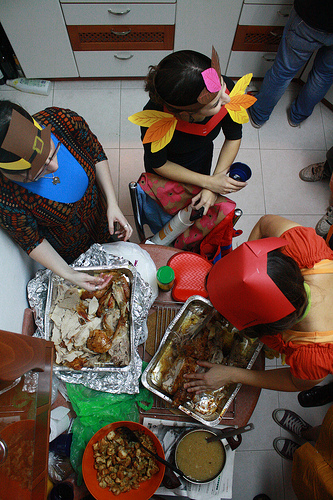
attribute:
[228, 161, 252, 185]
plastic cup — blue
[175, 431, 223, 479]
gravy — brown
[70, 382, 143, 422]
plastic bag — green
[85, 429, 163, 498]
bowl — red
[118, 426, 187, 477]
spoon — black, plastic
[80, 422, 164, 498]
bowl — red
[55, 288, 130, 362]
turkey — carved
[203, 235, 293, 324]
hat — red, paper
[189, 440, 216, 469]
sauce — brown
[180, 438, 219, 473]
sauce — brown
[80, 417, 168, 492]
bowl — orange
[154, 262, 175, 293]
jar — green in color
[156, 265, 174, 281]
lid — green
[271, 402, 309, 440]
shoe — blck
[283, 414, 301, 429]
laces — white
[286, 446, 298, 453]
laces — white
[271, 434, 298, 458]
shoe — blck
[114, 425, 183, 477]
spoon — black 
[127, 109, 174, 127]
leaf — yellow  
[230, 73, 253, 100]
leaf — yellow  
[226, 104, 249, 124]
leaf — yellow  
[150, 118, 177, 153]
leaf — yellow  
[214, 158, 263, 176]
cup — blue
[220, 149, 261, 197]
glass — blue